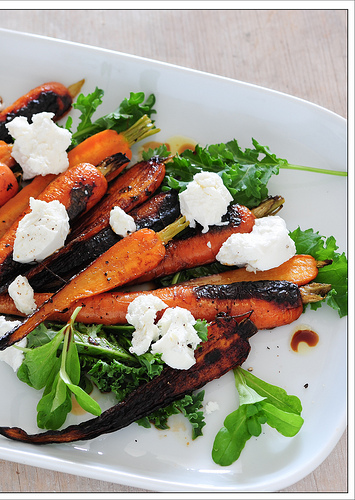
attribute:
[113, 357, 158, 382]
kale — green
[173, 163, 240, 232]
cheese — chunk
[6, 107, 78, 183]
cheese — chunk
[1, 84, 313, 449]
carrot — roasted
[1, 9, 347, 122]
table — wood 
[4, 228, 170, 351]
root vegetable — blackened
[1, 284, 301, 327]
root vegetable — blackened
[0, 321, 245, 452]
root vegetable — blackened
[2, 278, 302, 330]
root vegetable — blackened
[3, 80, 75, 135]
root vegetable — blackened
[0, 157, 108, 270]
carrot — grilled, baby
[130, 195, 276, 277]
carrot — grilled, baby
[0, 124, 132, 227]
carrot — grilled, baby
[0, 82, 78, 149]
carrot — grilled, baby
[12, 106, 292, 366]
cheese — soft, white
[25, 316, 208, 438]
lettuce — green 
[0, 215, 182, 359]
carrots — grilled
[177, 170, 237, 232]
white cheese — clumped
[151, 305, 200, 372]
cheese — fresh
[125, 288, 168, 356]
cheese — fresh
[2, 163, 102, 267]
carrot — grilled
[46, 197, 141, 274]
carrot — grilled, black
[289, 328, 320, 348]
sauce — small spot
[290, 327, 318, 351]
juice — small spot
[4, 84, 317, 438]
veggies — root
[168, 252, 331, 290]
carrot — sliced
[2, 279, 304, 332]
carrot — grilled, baby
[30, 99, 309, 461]
veggies — roasted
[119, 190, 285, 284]
carrot — roasted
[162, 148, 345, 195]
leaves — green 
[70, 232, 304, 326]
carrots — orange, black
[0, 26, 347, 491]
plate — white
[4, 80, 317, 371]
carrot — burnt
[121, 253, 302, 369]
carrot — burnt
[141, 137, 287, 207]
leaves — green, lettuce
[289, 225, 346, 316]
leaves — green, lettuce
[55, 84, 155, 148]
leaves — green, lettuce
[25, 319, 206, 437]
leaves — green, lettuce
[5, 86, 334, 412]
plate — white 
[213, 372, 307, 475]
herb — leafy, green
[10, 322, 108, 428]
herb — leafy, green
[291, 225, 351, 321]
herb — leafy, green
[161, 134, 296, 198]
herb — leafy, green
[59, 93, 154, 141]
herb — leafy, green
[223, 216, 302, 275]
cheese — soft, white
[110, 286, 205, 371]
cheese — soft, white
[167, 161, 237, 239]
cheese — soft, white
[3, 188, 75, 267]
cheese — soft, white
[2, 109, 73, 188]
cheese — soft, white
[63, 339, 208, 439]
kale — green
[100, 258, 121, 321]
grains — pepper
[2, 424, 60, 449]
tip — shriveled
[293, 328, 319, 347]
sauce — brown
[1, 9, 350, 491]
table — white